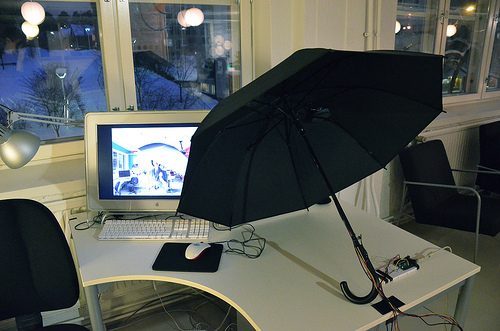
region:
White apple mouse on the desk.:
[172, 229, 210, 283]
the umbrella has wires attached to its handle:
[321, 216, 449, 310]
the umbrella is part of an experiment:
[326, 218, 435, 305]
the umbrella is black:
[151, 42, 483, 311]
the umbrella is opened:
[158, 49, 455, 315]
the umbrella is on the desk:
[172, 43, 479, 308]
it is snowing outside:
[9, 39, 118, 132]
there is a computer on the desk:
[55, 99, 284, 283]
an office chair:
[1, 197, 89, 319]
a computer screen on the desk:
[89, 120, 219, 207]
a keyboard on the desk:
[102, 213, 199, 235]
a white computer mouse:
[186, 237, 207, 259]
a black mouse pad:
[155, 241, 225, 275]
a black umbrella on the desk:
[181, 38, 465, 308]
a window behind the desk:
[2, 0, 228, 136]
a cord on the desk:
[227, 219, 256, 254]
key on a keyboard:
[106, 220, 112, 229]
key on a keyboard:
[126, 225, 131, 232]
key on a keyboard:
[140, 219, 151, 227]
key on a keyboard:
[139, 222, 146, 227]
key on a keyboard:
[135, 230, 145, 235]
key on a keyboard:
[149, 224, 159, 229]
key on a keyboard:
[176, 225, 182, 230]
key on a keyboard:
[191, 224, 198, 232]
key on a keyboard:
[174, 228, 183, 235]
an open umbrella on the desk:
[171, 63, 425, 328]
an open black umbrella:
[152, 65, 450, 264]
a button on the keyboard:
[114, 228, 131, 233]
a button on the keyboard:
[161, 222, 171, 227]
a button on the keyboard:
[186, 226, 192, 234]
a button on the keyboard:
[113, 227, 129, 235]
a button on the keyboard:
[111, 233, 131, 243]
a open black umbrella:
[175, 43, 445, 312]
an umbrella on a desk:
[3, 44, 493, 329]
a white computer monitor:
[80, 107, 207, 212]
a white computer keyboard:
[95, 217, 213, 239]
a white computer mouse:
[177, 238, 212, 258]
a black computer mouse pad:
[150, 240, 221, 270]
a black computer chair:
[0, 190, 91, 330]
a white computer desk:
[61, 193, 481, 328]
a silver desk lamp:
[0, 105, 85, 166]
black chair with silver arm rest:
[394, 139, 499, 266]